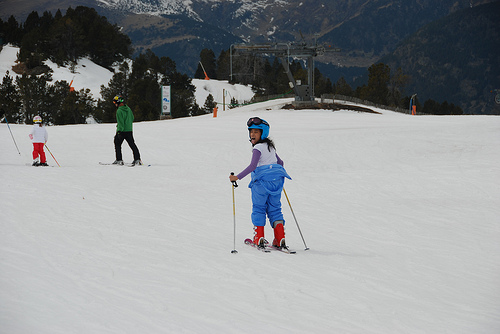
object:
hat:
[246, 116, 270, 140]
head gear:
[246, 116, 270, 139]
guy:
[112, 93, 141, 165]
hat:
[112, 94, 125, 106]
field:
[37, 116, 492, 315]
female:
[229, 117, 296, 255]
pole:
[213, 107, 217, 117]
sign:
[161, 85, 171, 112]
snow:
[1, 43, 498, 332]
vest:
[252, 142, 278, 167]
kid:
[28, 115, 48, 166]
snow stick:
[282, 189, 309, 251]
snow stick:
[230, 171, 235, 253]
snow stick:
[42, 144, 62, 169]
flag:
[69, 79, 74, 92]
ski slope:
[0, 106, 499, 333]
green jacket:
[116, 104, 135, 132]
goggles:
[246, 117, 269, 127]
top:
[236, 142, 292, 186]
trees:
[19, 10, 128, 67]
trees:
[199, 44, 284, 80]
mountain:
[4, 7, 482, 75]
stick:
[40, 140, 60, 168]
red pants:
[32, 142, 46, 163]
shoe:
[271, 220, 285, 248]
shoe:
[252, 226, 264, 246]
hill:
[3, 34, 173, 117]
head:
[247, 116, 271, 143]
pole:
[281, 184, 311, 250]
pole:
[230, 176, 238, 253]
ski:
[271, 239, 297, 254]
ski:
[243, 237, 274, 253]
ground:
[0, 93, 499, 331]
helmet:
[112, 94, 124, 107]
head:
[113, 95, 126, 108]